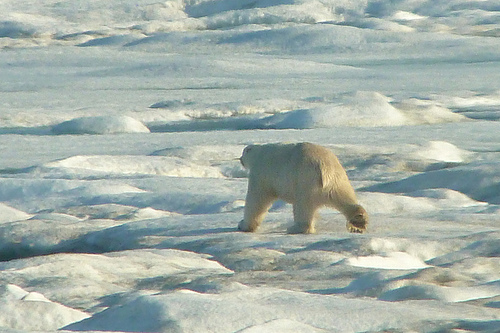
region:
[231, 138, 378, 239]
white polar bear facing away from camera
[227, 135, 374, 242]
white polar facing left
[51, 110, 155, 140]
small hill of snow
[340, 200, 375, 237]
bear's right rear paw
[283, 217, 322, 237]
bear's left rear paw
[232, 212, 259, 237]
bear's front left paw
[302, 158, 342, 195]
white polar bear's tail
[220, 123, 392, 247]
polar bear walking in snow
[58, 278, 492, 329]
small hill of snow in foreground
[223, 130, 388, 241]
white polar bear walking away from camera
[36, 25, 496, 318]
picture taken outdoors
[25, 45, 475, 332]
Picture taken during the day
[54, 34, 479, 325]
A polar bear walking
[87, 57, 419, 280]
The polar bear is in the Arctic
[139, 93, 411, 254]
The polar bear is NOT in the Antarctic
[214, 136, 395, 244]
The polar bear is white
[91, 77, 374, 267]
Snow covers the vast ground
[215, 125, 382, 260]
The polar bear is by himself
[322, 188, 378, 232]
The polar bear's leg is up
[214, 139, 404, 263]
The polar bear is big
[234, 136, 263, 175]
Head of a bear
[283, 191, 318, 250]
Leg of a bear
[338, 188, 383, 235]
Leg of a bear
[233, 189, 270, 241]
Leg of a bear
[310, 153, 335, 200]
Tail of a bear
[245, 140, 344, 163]
Back of a bear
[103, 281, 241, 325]
Haep of a Ice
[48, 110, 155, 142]
Haep of a Ice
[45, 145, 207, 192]
Haep of a Ice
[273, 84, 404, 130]
Haep of a Ice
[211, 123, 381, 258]
white polar bear walking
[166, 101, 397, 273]
a polar bear walking across the snow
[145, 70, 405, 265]
a polar bear walking across the ice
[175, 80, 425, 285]
a polar bear on a glacier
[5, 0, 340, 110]
ice and snow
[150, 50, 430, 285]
a polar bear in a cold place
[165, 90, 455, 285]
a large polar bear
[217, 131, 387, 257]
a white polar bear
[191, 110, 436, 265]
a big white polar bear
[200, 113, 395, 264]
a large polar bear walking across ice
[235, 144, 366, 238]
white colored polar bear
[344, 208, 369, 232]
large polar bear foot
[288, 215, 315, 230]
large polar bear foot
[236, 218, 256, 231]
large polar bear foot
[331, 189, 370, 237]
large polar bear leg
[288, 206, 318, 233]
large polar bear leg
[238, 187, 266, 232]
large polar bear leg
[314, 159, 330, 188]
short polar bear tail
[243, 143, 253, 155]
small polar bear ear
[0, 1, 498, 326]
ground covered in snow